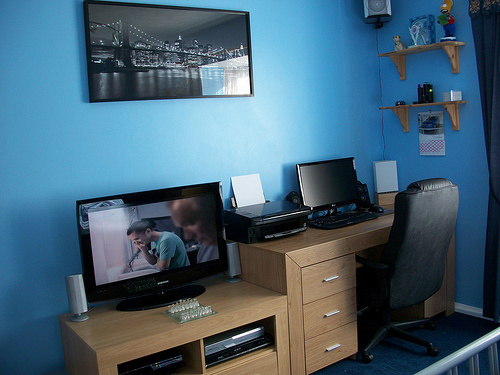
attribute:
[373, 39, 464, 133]
shelves — wooden, hanging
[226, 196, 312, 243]
printer — black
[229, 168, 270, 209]
paper — white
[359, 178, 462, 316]
leather — black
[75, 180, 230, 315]
tv — flat, screen, black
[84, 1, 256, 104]
photograph — black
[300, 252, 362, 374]
drawers — three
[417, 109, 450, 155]
calendar — hung, small, red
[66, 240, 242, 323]
speakers — silver, white, mounted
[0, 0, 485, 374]
walls — blue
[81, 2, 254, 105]
picture — framed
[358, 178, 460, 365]
chair — black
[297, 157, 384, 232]
cpu — black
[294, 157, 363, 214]
monitor — black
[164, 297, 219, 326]
set — glass